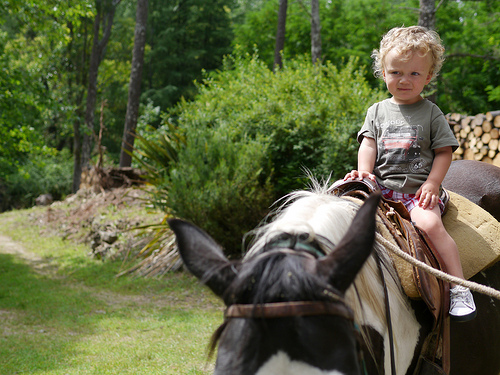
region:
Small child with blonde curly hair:
[365, 26, 440, 109]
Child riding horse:
[327, 53, 463, 256]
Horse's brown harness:
[221, 244, 363, 353]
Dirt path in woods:
[2, 233, 153, 338]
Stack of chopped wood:
[455, 113, 498, 170]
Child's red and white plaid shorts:
[377, 180, 442, 212]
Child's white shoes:
[441, 276, 484, 320]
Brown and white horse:
[218, 178, 425, 374]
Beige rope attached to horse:
[380, 231, 498, 314]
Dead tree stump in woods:
[87, 108, 124, 197]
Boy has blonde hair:
[375, 28, 439, 96]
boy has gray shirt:
[353, 100, 455, 203]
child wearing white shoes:
[447, 279, 478, 326]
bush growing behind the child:
[139, 47, 361, 229]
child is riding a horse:
[171, 21, 499, 373]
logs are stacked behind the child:
[444, 105, 499, 181]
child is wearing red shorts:
[380, 190, 450, 210]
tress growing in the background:
[56, 10, 154, 192]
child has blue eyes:
[389, 69, 422, 76]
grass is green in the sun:
[86, 307, 204, 367]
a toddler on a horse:
[334, 11, 489, 333]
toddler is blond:
[348, 17, 460, 135]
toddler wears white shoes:
[341, 13, 486, 335]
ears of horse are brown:
[147, 189, 388, 304]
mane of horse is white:
[256, 165, 390, 314]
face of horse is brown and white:
[198, 307, 350, 373]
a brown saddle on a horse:
[317, 173, 489, 325]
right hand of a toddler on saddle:
[321, 19, 471, 216]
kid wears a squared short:
[336, 13, 483, 329]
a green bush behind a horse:
[153, 35, 373, 255]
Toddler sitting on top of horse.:
[345, 7, 492, 321]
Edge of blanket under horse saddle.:
[451, 188, 497, 277]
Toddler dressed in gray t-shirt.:
[356, 91, 456, 191]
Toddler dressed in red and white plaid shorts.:
[378, 183, 457, 218]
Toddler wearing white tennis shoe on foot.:
[444, 280, 487, 324]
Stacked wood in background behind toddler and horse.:
[451, 106, 498, 161]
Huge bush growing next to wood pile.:
[137, 40, 362, 255]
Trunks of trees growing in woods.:
[58, 8, 155, 189]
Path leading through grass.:
[8, 238, 194, 311]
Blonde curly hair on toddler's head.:
[372, 22, 443, 71]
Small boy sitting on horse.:
[360, 27, 477, 317]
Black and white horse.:
[231, 130, 493, 369]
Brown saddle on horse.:
[310, 129, 453, 303]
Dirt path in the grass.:
[7, 225, 104, 320]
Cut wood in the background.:
[444, 98, 499, 177]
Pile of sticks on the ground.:
[127, 222, 177, 287]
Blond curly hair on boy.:
[370, 35, 453, 94]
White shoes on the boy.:
[428, 229, 475, 328]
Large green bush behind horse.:
[170, 48, 290, 201]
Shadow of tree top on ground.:
[20, 215, 145, 370]